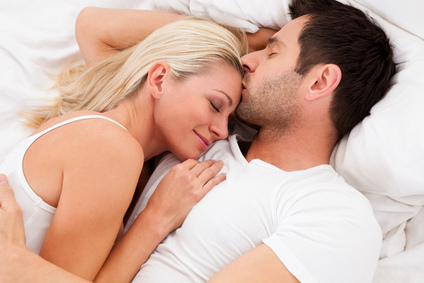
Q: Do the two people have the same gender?
A: No, they are both male and female.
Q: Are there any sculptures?
A: No, there are no sculptures.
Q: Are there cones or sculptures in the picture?
A: No, there are no sculptures or cones.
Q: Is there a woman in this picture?
A: Yes, there is a woman.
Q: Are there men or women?
A: Yes, there is a woman.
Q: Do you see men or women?
A: Yes, there is a woman.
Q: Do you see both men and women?
A: Yes, there are both a woman and a man.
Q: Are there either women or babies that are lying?
A: Yes, the woman is lying.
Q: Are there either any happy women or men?
A: Yes, there is a happy woman.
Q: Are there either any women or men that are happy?
A: Yes, the woman is happy.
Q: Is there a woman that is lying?
A: Yes, there is a woman that is lying.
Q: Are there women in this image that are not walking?
A: Yes, there is a woman that is lying.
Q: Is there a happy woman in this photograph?
A: Yes, there is a happy woman.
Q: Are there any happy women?
A: Yes, there is a happy woman.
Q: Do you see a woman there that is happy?
A: Yes, there is a woman that is happy.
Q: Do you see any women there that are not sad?
A: Yes, there is a happy woman.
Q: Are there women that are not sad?
A: Yes, there is a happy woman.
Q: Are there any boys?
A: No, there are no boys.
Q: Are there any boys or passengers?
A: No, there are no boys or passengers.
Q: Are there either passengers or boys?
A: No, there are no boys or passengers.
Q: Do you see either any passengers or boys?
A: No, there are no boys or passengers.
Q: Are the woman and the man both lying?
A: Yes, both the woman and the man are lying.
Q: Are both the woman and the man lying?
A: Yes, both the woman and the man are lying.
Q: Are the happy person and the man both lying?
A: Yes, both the woman and the man are lying.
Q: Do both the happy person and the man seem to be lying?
A: Yes, both the woman and the man are lying.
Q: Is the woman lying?
A: Yes, the woman is lying.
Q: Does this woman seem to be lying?
A: Yes, the woman is lying.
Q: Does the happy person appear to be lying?
A: Yes, the woman is lying.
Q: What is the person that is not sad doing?
A: The woman is lying.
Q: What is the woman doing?
A: The woman is lying.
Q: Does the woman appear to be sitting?
A: No, the woman is lying.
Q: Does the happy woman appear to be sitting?
A: No, the woman is lying.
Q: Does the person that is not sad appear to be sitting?
A: No, the woman is lying.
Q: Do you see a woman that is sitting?
A: No, there is a woman but she is lying.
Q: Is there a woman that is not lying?
A: No, there is a woman but she is lying.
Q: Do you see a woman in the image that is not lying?
A: No, there is a woman but she is lying.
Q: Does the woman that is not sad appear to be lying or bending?
A: The woman is lying.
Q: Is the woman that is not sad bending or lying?
A: The woman is lying.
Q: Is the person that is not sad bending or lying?
A: The woman is lying.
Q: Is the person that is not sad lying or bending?
A: The woman is lying.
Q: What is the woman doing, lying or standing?
A: The woman is lying.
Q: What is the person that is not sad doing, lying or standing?
A: The woman is lying.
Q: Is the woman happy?
A: Yes, the woman is happy.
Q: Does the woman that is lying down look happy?
A: Yes, the woman is happy.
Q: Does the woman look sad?
A: No, the woman is happy.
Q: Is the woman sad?
A: No, the woman is happy.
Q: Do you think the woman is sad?
A: No, the woman is happy.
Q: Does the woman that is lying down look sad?
A: No, the woman is happy.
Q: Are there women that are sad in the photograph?
A: No, there is a woman but she is happy.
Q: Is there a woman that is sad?
A: No, there is a woman but she is happy.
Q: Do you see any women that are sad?
A: No, there is a woman but she is happy.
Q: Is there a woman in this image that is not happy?
A: No, there is a woman but she is happy.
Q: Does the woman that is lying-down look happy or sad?
A: The woman is happy.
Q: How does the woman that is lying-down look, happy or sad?
A: The woman is happy.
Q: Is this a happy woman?
A: Yes, this is a happy woman.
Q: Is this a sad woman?
A: No, this is a happy woman.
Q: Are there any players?
A: No, there are no players.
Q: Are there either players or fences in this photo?
A: No, there are no players or fences.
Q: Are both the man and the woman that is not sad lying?
A: Yes, both the man and the woman are lying.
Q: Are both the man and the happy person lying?
A: Yes, both the man and the woman are lying.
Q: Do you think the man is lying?
A: Yes, the man is lying.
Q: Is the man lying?
A: Yes, the man is lying.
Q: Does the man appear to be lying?
A: Yes, the man is lying.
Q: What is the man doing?
A: The man is lying.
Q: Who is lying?
A: The man is lying.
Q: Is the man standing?
A: No, the man is lying.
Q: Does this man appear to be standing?
A: No, the man is lying.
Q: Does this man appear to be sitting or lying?
A: The man is lying.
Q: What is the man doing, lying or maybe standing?
A: The man is lying.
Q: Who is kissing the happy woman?
A: The man is kissing the woman.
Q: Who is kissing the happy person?
A: The man is kissing the woman.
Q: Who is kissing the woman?
A: The man is kissing the woman.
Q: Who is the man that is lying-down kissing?
A: The man is kissing the woman.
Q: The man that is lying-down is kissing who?
A: The man is kissing the woman.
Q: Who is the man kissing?
A: The man is kissing the woman.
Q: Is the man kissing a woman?
A: Yes, the man is kissing a woman.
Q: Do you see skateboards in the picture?
A: No, there are no skateboards.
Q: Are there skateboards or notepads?
A: No, there are no skateboards or notepads.